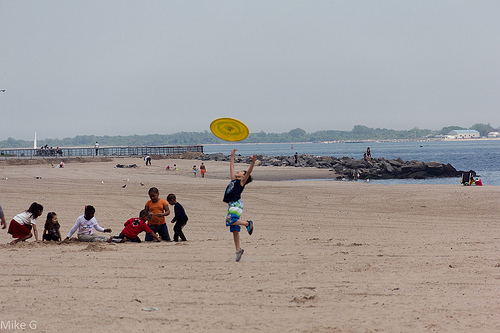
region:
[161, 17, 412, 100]
The sky is gray.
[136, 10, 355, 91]
The sky is overcast.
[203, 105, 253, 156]
The frisbee is yellow.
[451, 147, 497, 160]
The water is blue.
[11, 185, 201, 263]
People are on the beach.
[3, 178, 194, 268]
People are playing in the sand.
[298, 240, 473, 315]
The sand is tan.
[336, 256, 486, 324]
Sand is on the beach.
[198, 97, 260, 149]
A frisbee is in the air.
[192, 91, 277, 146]
The frisbee is large.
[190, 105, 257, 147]
the frisbee is yellow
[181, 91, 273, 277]
the person is playing with the frisbee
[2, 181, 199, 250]
the kids are playing in the sand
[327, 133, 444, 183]
a person is sitting on the rocks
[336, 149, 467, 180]
the rocks are dark grey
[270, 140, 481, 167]
the water is calm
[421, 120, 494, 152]
a white house in the distance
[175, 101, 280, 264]
the kid is jumping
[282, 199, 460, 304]
the sand is beige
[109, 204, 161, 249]
the little boy is wearing a red shirt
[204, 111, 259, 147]
large yellow frisbee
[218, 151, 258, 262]
boy with black top and colorful shorts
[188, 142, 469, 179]
large expanse of rocks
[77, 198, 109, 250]
girl dressed in a white outfit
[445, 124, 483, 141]
blue and white building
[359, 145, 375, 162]
girl sitting on the rocks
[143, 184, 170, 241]
girl in an orange t-shirt and black trousers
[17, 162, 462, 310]
large sandy beach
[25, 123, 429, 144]
green trees on the shore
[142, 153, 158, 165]
a person bending over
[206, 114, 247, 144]
a yellow frisbee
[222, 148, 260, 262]
a young child jumping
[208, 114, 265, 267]
young boy trying to catch frisbee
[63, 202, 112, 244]
child playing in sand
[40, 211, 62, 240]
child playing in sand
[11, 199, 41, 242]
child playing in sand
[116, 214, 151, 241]
child playing in sand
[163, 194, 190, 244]
child playing in sand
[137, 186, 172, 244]
adult kneeling in sand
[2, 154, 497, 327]
large brown sandy beach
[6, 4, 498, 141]
a hazy grey sky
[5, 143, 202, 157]
a long wooden pier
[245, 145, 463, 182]
a grey rocky beach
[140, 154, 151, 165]
a person bending over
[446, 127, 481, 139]
a large building in distance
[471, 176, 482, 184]
a red and white cooler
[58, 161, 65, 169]
a person sitting in sand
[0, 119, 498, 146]
a long tree line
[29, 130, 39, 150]
a white sail boat sail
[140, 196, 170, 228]
an orange t-shirt